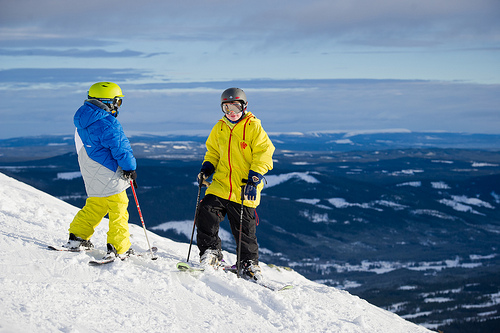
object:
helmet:
[89, 82, 126, 102]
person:
[193, 85, 276, 277]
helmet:
[219, 87, 250, 110]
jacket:
[204, 112, 273, 209]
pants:
[197, 189, 260, 267]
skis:
[88, 246, 158, 266]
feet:
[103, 243, 134, 262]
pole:
[127, 174, 158, 260]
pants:
[68, 189, 134, 253]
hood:
[74, 100, 114, 126]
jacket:
[74, 99, 131, 202]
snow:
[0, 167, 421, 333]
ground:
[0, 168, 438, 332]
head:
[216, 84, 252, 124]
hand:
[115, 162, 136, 180]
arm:
[100, 123, 138, 172]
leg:
[110, 193, 130, 255]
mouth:
[229, 114, 239, 120]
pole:
[236, 184, 246, 278]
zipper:
[227, 126, 233, 201]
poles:
[185, 174, 204, 262]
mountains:
[10, 131, 499, 177]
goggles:
[221, 99, 245, 115]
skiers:
[46, 79, 158, 265]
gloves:
[243, 169, 263, 202]